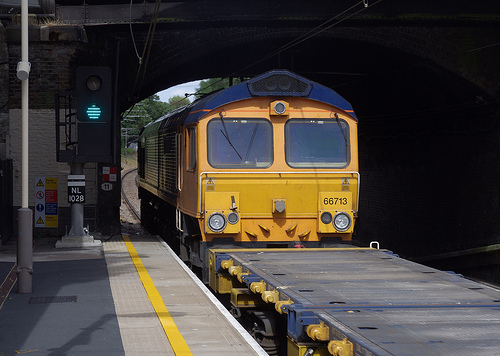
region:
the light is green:
[68, 102, 117, 133]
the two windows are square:
[191, 116, 386, 254]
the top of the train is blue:
[178, 73, 361, 110]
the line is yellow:
[108, 251, 203, 353]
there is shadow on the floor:
[66, 293, 183, 354]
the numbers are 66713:
[310, 191, 362, 211]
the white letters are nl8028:
[66, 181, 108, 210]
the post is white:
[4, 96, 46, 192]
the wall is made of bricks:
[38, 81, 52, 157]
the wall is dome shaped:
[154, 33, 481, 88]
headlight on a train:
[205, 206, 226, 238]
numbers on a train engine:
[320, 188, 356, 207]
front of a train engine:
[175, 63, 375, 243]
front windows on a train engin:
[194, 111, 356, 177]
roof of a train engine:
[157, 69, 397, 114]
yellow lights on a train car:
[216, 254, 248, 284]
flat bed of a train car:
[230, 245, 491, 327]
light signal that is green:
[38, 31, 133, 263]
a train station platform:
[131, 237, 276, 351]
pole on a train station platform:
[3, 6, 56, 291]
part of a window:
[211, 122, 252, 155]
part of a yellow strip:
[141, 297, 183, 342]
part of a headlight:
[213, 212, 233, 229]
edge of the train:
[313, 81, 344, 98]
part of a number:
[310, 197, 352, 208]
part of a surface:
[377, 272, 439, 318]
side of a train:
[139, 117, 196, 190]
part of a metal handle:
[172, 129, 191, 193]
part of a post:
[14, 155, 41, 217]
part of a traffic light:
[71, 72, 111, 134]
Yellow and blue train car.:
[141, 67, 352, 261]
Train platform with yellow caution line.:
[103, 233, 260, 353]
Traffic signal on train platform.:
[49, 49, 124, 252]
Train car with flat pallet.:
[188, 231, 495, 353]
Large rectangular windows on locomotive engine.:
[201, 100, 356, 178]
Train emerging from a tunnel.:
[78, 19, 498, 280]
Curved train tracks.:
[109, 157, 152, 231]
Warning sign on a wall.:
[29, 173, 62, 228]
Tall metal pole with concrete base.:
[8, 2, 66, 293]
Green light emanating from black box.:
[80, 98, 105, 121]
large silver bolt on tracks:
[363, 233, 407, 262]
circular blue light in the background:
[75, 99, 107, 132]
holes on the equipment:
[332, 290, 392, 338]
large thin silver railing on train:
[198, 169, 380, 179]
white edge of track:
[209, 315, 257, 353]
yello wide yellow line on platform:
[135, 295, 189, 327]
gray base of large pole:
[6, 199, 49, 289]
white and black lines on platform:
[58, 166, 102, 217]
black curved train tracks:
[128, 161, 143, 231]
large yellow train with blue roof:
[166, 60, 394, 275]